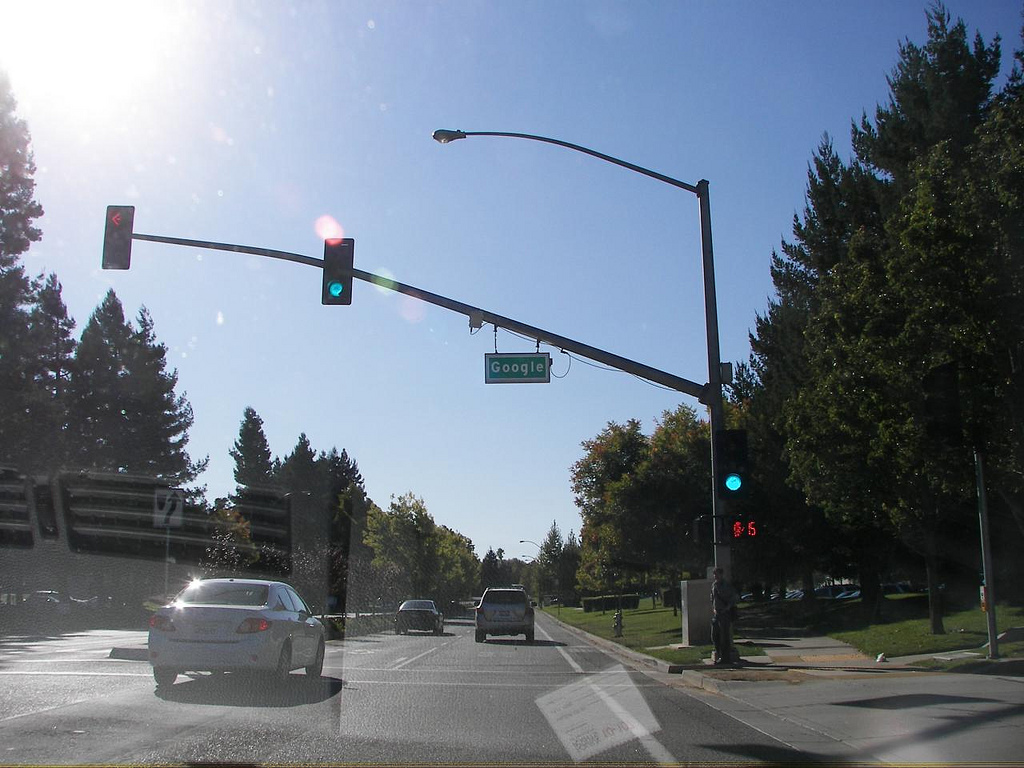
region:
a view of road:
[364, 639, 481, 756]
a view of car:
[108, 456, 331, 704]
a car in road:
[142, 518, 345, 714]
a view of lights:
[237, 574, 335, 679]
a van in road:
[419, 538, 642, 754]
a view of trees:
[220, 445, 449, 566]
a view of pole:
[623, 310, 753, 586]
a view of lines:
[546, 641, 645, 753]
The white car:
[125, 560, 332, 687]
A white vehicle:
[132, 559, 357, 699]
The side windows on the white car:
[268, 589, 310, 618]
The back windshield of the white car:
[181, 569, 280, 614]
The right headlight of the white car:
[238, 611, 278, 638]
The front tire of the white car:
[309, 638, 335, 673]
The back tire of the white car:
[270, 643, 300, 689]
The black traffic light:
[93, 197, 145, 273]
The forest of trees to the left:
[1, 76, 501, 601]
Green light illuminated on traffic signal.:
[318, 275, 353, 305]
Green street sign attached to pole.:
[451, 338, 584, 378]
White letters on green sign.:
[470, 348, 566, 386]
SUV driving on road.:
[474, 584, 536, 652]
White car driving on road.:
[155, 595, 353, 688]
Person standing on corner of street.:
[694, 560, 745, 658]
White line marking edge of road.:
[540, 601, 665, 766]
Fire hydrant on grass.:
[600, 601, 635, 650]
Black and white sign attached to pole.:
[151, 484, 186, 565]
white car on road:
[155, 537, 321, 700]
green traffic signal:
[304, 206, 400, 358]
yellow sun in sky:
[17, 4, 221, 156]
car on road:
[119, 569, 303, 680]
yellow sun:
[23, 19, 233, 179]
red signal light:
[710, 508, 762, 563]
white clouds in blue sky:
[242, 63, 329, 130]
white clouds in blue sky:
[444, 180, 493, 247]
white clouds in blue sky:
[558, 215, 634, 302]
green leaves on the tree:
[858, 318, 885, 354]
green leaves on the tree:
[968, 311, 988, 350]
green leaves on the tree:
[836, 322, 893, 405]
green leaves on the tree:
[924, 147, 1004, 249]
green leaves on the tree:
[883, 132, 945, 190]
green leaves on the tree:
[785, 343, 824, 427]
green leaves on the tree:
[630, 504, 668, 534]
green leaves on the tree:
[610, 439, 652, 526]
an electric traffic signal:
[99, 206, 135, 271]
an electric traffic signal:
[323, 234, 352, 302]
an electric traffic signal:
[715, 424, 751, 498]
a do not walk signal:
[727, 504, 766, 542]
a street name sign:
[481, 348, 552, 384]